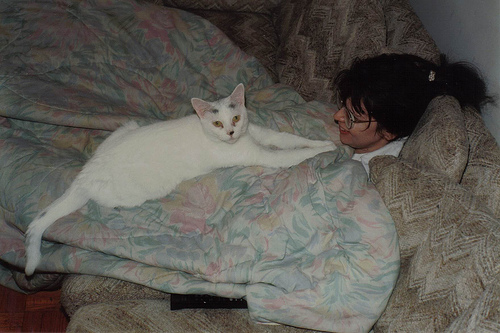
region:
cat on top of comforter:
[6, 85, 357, 311]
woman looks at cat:
[56, 41, 486, 232]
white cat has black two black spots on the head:
[57, 82, 338, 221]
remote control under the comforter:
[164, 272, 266, 325]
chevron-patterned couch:
[59, 0, 494, 325]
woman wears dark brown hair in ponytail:
[335, 36, 485, 175]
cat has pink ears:
[176, 75, 326, 198]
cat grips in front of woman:
[58, 77, 370, 249]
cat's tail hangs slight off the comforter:
[14, 90, 89, 312]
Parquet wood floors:
[3, 261, 65, 331]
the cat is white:
[61, 87, 336, 329]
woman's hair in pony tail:
[325, 36, 466, 147]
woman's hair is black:
[324, 36, 489, 167]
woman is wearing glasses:
[326, 86, 372, 136]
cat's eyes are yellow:
[203, 111, 257, 133]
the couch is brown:
[193, 2, 494, 330]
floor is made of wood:
[1, 276, 89, 330]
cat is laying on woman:
[20, 48, 472, 233]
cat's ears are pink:
[175, 82, 266, 114]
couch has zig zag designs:
[350, 156, 477, 322]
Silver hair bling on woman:
[424, 65, 438, 90]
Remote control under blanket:
[165, 285, 255, 315]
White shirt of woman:
[348, 136, 421, 164]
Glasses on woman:
[325, 85, 373, 127]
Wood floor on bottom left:
[0, 275, 82, 329]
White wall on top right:
[404, 0, 496, 139]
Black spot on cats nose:
[223, 128, 236, 136]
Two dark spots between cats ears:
[209, 100, 235, 115]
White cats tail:
[19, 162, 90, 287]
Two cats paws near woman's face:
[315, 132, 337, 164]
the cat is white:
[68, 85, 270, 229]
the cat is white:
[121, 95, 324, 251]